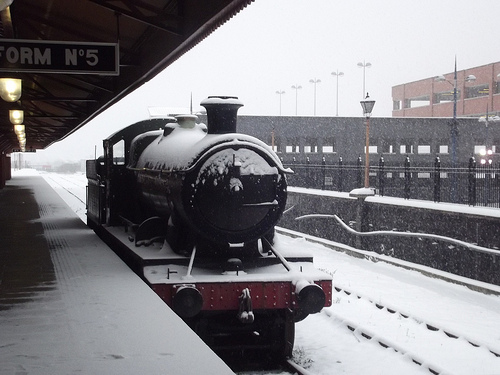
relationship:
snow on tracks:
[318, 243, 495, 369] [43, 171, 499, 373]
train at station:
[88, 104, 338, 359] [1, 0, 270, 372]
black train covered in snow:
[102, 87, 347, 338] [148, 123, 281, 171]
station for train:
[1, 0, 270, 372] [79, 119, 329, 318]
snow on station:
[5, 168, 499, 373] [2, 3, 499, 373]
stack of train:
[199, 90, 245, 133] [62, 126, 324, 256]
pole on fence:
[327, 102, 378, 199] [273, 154, 498, 211]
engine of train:
[103, 95, 331, 363] [88, 104, 338, 359]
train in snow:
[88, 104, 338, 359] [293, 237, 498, 372]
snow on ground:
[5, 168, 499, 373] [40, 169, 498, 374]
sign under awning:
[3, 34, 115, 83] [132, 17, 215, 67]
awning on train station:
[132, 17, 215, 67] [0, 3, 252, 372]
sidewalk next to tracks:
[2, 177, 234, 374] [43, 171, 499, 373]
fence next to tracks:
[274, 185, 499, 297] [43, 171, 499, 373]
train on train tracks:
[85, 92, 331, 359] [302, 263, 475, 374]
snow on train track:
[5, 168, 499, 373] [43, 171, 498, 373]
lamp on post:
[356, 87, 376, 118] [361, 121, 373, 188]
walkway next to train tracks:
[2, 165, 232, 373] [267, 223, 499, 374]